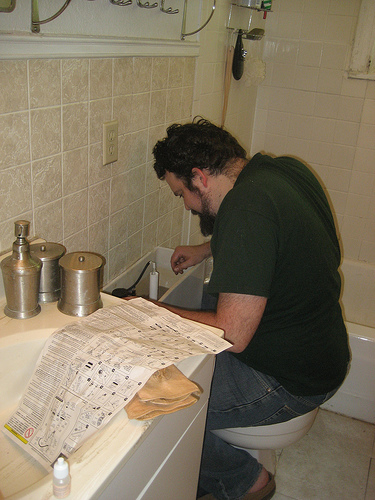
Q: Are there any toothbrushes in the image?
A: No, there are no toothbrushes.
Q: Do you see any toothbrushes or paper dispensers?
A: No, there are no toothbrushes or paper dispensers.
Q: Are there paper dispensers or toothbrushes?
A: No, there are no toothbrushes or paper dispensers.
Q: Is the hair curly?
A: Yes, the hair is curly.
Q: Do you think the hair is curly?
A: Yes, the hair is curly.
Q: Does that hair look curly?
A: Yes, the hair is curly.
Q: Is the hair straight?
A: No, the hair is curly.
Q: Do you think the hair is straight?
A: No, the hair is curly.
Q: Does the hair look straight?
A: No, the hair is curly.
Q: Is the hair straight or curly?
A: The hair is curly.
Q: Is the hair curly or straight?
A: The hair is curly.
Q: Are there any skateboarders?
A: No, there are no skateboarders.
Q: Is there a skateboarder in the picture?
A: No, there are no skateboarders.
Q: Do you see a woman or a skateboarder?
A: No, there are no skateboarders or women.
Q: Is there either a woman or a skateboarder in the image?
A: No, there are no skateboarders or women.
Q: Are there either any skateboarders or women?
A: No, there are no skateboarders or women.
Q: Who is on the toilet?
A: The man is on the toilet.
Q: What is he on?
A: The man is on the toilet.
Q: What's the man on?
A: The man is on the toilet.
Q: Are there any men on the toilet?
A: Yes, there is a man on the toilet.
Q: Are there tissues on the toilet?
A: No, there is a man on the toilet.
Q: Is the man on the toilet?
A: Yes, the man is on the toilet.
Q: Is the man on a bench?
A: No, the man is on the toilet.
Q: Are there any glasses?
A: No, there are no glasses.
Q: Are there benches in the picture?
A: No, there are no benches.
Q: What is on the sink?
A: The newspaper is on the sink.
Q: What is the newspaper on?
A: The newspaper is on the sink.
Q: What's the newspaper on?
A: The newspaper is on the sink.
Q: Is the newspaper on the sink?
A: Yes, the newspaper is on the sink.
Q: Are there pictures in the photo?
A: No, there are no pictures.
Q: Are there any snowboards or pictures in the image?
A: No, there are no pictures or snowboards.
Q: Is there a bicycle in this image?
A: No, there are no bicycles.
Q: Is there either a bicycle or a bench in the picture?
A: No, there are no bicycles or benches.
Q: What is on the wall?
A: The outlet is on the wall.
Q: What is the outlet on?
A: The outlet is on the wall.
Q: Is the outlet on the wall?
A: Yes, the outlet is on the wall.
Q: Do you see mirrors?
A: No, there are no mirrors.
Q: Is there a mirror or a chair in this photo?
A: No, there are no mirrors or chairs.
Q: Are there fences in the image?
A: No, there are no fences.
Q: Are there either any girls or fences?
A: No, there are no fences or girls.